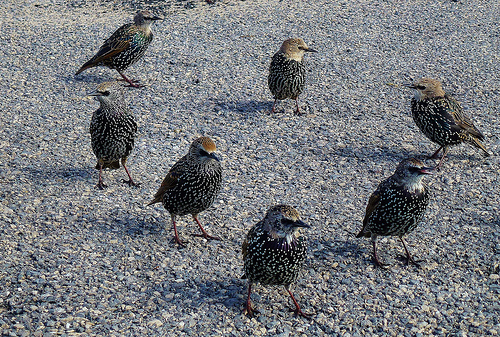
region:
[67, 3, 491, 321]
Flock of birds on asphalt pavement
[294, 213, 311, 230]
Black beak of bird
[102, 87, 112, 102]
Black eye of bird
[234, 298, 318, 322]
Extended claws on bird's feet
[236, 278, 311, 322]
Legs of small bird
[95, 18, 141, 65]
Folded wing of bird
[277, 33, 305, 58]
White feathered head of bird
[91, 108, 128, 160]
Multicolored feathered breast of bird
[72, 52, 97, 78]
Tail feathers of bird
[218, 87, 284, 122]
Shadow of bird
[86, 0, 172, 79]
black bird standing on pebbles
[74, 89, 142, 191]
black bird standing on pebbles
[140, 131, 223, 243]
black bird standing on pebbles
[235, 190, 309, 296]
black bird standing on pebbles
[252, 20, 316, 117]
black bird standing on pebbles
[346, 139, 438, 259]
black bird standing on pebbles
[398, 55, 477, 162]
black bird standing on pebbles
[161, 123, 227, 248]
black bird standing on gray pebbles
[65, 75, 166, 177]
black bird standing on gray pebbles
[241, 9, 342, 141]
black bird standing on gray pebbles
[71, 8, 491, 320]
Group of little birds on the ground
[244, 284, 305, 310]
Little red legs of bird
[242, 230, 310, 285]
White speckled body of bird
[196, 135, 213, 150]
Brown spot on bird's head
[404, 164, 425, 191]
Grey feathers on bird's throat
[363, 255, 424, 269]
Black feet of bird in gravel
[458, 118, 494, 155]
Long tail of bird close to the ground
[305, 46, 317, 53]
Sharp black beak of bird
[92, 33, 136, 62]
Brown and white feathers on bird's wing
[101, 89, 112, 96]
Black eye on side of bird's face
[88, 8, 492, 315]
birds standing on pavement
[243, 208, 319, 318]
a black bird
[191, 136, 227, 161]
the head of a bird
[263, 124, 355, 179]
the pavement on the road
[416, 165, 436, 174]
the beak of the bird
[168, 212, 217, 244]
the legs of the bird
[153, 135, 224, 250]
a bird with a brown head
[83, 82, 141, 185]
a bird looking to the right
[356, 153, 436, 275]
a white and black bird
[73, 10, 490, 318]
seven birds on the pavement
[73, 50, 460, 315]
the birds are in a group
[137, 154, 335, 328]
the black and white birds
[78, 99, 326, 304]
the birds are standing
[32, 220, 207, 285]
rocks are on the ground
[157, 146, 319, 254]
birds are standing on rocks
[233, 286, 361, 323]
the bird's feet are brown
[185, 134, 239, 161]
the bird has a brown head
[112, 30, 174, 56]
the feathers are green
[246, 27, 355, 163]
the bird is small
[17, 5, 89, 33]
the rocks are light colored